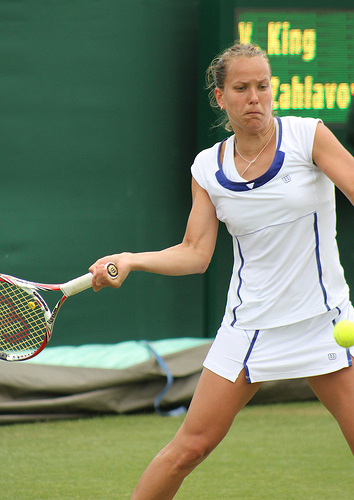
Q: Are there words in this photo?
A: Yes, there are words.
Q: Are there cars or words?
A: Yes, there are words.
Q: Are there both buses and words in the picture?
A: No, there are words but no buses.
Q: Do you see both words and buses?
A: No, there are words but no buses.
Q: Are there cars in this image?
A: No, there are no cars.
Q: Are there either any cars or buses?
A: No, there are no cars or buses.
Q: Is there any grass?
A: Yes, there is grass.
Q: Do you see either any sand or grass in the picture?
A: Yes, there is grass.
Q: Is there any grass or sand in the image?
A: Yes, there is grass.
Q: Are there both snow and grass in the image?
A: No, there is grass but no snow.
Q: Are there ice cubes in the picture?
A: No, there are no ice cubes.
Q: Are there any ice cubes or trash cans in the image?
A: No, there are no ice cubes or trash cans.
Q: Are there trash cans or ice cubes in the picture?
A: No, there are no ice cubes or trash cans.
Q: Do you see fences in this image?
A: No, there are no fences.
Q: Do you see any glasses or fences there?
A: No, there are no fences or glasses.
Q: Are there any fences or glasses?
A: No, there are no fences or glasses.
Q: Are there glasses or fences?
A: No, there are no fences or glasses.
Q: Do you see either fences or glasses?
A: No, there are no fences or glasses.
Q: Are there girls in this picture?
A: No, there are no girls.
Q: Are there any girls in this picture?
A: No, there are no girls.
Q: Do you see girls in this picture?
A: No, there are no girls.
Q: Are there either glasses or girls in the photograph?
A: No, there are no girls or glasses.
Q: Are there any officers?
A: No, there are no officers.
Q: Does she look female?
A: Yes, the player is female.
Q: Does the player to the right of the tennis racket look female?
A: Yes, the player is female.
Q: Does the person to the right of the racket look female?
A: Yes, the player is female.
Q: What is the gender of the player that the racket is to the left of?
A: The player is female.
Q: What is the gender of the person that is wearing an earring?
A: The player is female.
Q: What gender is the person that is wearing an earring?
A: The player is female.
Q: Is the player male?
A: No, the player is female.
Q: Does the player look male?
A: No, the player is female.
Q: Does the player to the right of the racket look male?
A: No, the player is female.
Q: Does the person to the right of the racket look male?
A: No, the player is female.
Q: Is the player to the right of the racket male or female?
A: The player is female.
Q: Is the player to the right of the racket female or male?
A: The player is female.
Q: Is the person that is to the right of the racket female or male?
A: The player is female.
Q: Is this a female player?
A: Yes, this is a female player.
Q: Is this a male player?
A: No, this is a female player.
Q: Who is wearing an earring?
A: The player is wearing an earring.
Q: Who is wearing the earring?
A: The player is wearing an earring.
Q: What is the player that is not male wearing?
A: The player is wearing an earring.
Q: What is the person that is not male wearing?
A: The player is wearing an earring.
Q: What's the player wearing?
A: The player is wearing an earring.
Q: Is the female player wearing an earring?
A: Yes, the player is wearing an earring.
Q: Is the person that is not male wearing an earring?
A: Yes, the player is wearing an earring.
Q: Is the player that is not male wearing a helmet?
A: No, the player is wearing an earring.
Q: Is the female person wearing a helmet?
A: No, the player is wearing an earring.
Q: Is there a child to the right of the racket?
A: No, there is a player to the right of the racket.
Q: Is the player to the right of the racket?
A: Yes, the player is to the right of the racket.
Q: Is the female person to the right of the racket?
A: Yes, the player is to the right of the racket.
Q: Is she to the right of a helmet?
A: No, the player is to the right of the racket.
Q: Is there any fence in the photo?
A: No, there are no fences.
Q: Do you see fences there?
A: No, there are no fences.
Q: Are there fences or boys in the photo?
A: No, there are no fences or boys.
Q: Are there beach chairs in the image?
A: No, there are no beach chairs.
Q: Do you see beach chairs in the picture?
A: No, there are no beach chairs.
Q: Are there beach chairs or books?
A: No, there are no beach chairs or books.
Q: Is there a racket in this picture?
A: Yes, there is a racket.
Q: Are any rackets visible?
A: Yes, there is a racket.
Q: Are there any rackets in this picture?
A: Yes, there is a racket.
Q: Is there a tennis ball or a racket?
A: Yes, there is a racket.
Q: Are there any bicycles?
A: No, there are no bicycles.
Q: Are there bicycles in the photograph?
A: No, there are no bicycles.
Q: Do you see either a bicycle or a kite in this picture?
A: No, there are no bicycles or kites.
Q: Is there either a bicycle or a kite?
A: No, there are no bicycles or kites.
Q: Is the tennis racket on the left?
A: Yes, the tennis racket is on the left of the image.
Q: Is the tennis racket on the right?
A: No, the tennis racket is on the left of the image.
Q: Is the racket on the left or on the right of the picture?
A: The racket is on the left of the image.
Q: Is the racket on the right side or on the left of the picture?
A: The racket is on the left of the image.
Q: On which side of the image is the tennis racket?
A: The tennis racket is on the left of the image.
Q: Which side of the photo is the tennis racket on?
A: The tennis racket is on the left of the image.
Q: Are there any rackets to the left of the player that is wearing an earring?
A: Yes, there is a racket to the left of the player.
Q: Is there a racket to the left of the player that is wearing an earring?
A: Yes, there is a racket to the left of the player.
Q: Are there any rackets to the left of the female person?
A: Yes, there is a racket to the left of the player.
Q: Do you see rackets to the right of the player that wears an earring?
A: No, the racket is to the left of the player.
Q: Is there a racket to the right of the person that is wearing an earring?
A: No, the racket is to the left of the player.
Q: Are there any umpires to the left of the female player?
A: No, there is a racket to the left of the player.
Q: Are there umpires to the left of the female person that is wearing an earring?
A: No, there is a racket to the left of the player.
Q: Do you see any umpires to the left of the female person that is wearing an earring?
A: No, there is a racket to the left of the player.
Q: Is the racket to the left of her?
A: Yes, the racket is to the left of the player.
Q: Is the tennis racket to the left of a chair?
A: No, the tennis racket is to the left of the player.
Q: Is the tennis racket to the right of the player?
A: No, the tennis racket is to the left of the player.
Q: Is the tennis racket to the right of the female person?
A: No, the tennis racket is to the left of the player.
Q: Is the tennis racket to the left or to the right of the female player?
A: The tennis racket is to the left of the player.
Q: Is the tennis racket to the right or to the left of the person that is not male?
A: The tennis racket is to the left of the player.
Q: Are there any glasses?
A: No, there are no glasses.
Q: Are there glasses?
A: No, there are no glasses.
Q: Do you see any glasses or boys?
A: No, there are no glasses or boys.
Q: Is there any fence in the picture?
A: No, there are no fences.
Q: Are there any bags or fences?
A: No, there are no fences or bags.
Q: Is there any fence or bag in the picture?
A: No, there are no fences or bags.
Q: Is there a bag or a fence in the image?
A: No, there are no fences or bags.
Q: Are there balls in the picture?
A: Yes, there is a ball.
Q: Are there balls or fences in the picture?
A: Yes, there is a ball.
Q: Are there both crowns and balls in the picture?
A: No, there is a ball but no crowns.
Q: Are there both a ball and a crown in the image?
A: No, there is a ball but no crowns.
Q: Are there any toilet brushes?
A: No, there are no toilet brushes.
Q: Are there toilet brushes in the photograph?
A: No, there are no toilet brushes.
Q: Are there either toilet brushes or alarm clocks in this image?
A: No, there are no toilet brushes or alarm clocks.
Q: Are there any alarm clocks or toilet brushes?
A: No, there are no toilet brushes or alarm clocks.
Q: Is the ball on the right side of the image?
A: Yes, the ball is on the right of the image.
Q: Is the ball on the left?
A: No, the ball is on the right of the image.